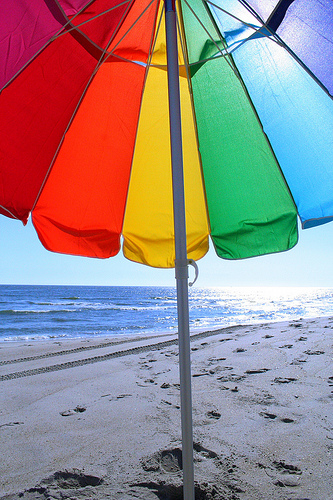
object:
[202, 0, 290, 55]
braces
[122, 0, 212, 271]
cloth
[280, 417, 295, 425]
sand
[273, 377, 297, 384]
footprint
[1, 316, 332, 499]
sand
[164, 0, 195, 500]
pole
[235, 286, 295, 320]
sun reflection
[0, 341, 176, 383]
tracks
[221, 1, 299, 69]
sun reflecting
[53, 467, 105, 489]
foot prints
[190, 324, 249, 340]
tracks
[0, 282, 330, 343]
water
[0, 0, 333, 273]
umbrella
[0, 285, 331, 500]
beach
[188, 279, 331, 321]
sunlight